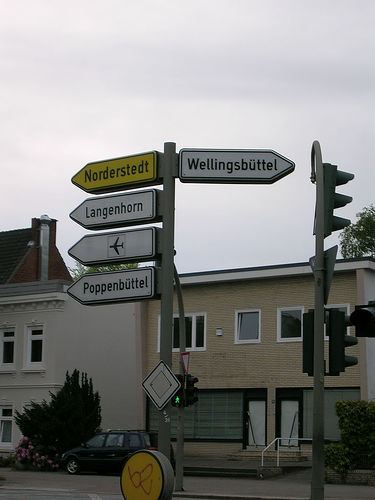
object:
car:
[59, 427, 175, 476]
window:
[173, 313, 196, 351]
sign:
[69, 189, 157, 229]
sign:
[68, 227, 154, 265]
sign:
[67, 266, 154, 306]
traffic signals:
[325, 307, 358, 377]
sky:
[0, 1, 375, 280]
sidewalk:
[185, 451, 312, 471]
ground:
[0, 466, 375, 500]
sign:
[178, 147, 295, 183]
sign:
[141, 360, 182, 411]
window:
[324, 303, 352, 342]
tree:
[13, 366, 102, 468]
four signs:
[67, 150, 156, 305]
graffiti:
[233, 306, 261, 345]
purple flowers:
[55, 462, 59, 469]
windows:
[102, 429, 126, 450]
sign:
[120, 451, 165, 499]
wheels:
[66, 458, 78, 475]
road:
[0, 455, 375, 500]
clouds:
[0, 0, 375, 247]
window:
[237, 311, 258, 340]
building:
[0, 213, 375, 463]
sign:
[71, 150, 158, 192]